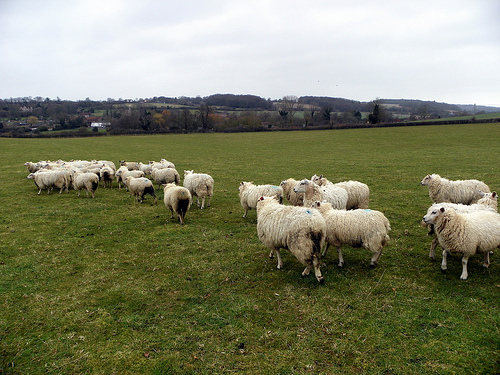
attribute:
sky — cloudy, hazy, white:
[66, 22, 85, 29]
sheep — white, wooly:
[246, 192, 333, 289]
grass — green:
[88, 273, 147, 308]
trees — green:
[129, 112, 186, 124]